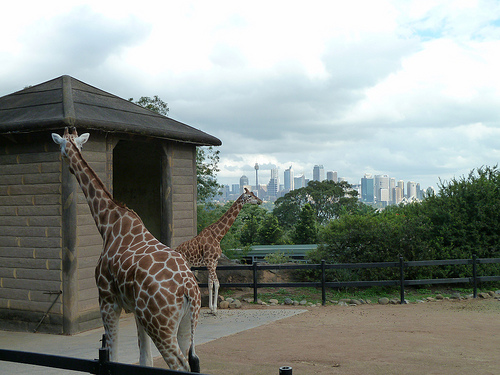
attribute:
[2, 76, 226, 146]
roof — brown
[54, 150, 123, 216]
head — tall 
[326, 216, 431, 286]
leaves — green 